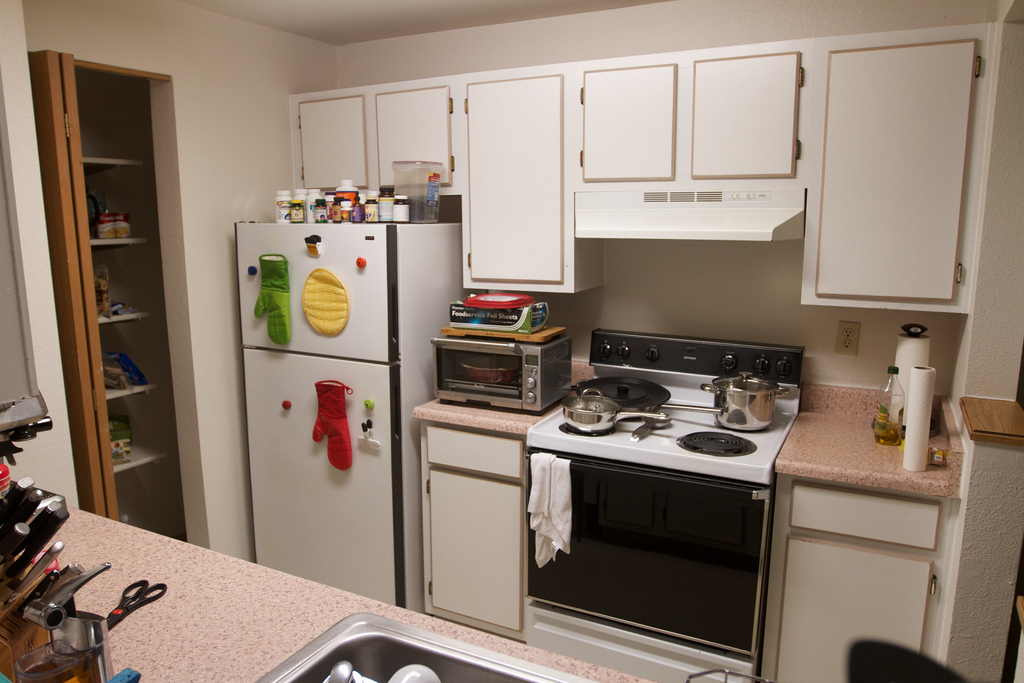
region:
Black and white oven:
[526, 325, 806, 680]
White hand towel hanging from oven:
[527, 447, 578, 577]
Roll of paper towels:
[902, 358, 937, 480]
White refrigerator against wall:
[235, 217, 469, 617]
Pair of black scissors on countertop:
[99, 575, 167, 632]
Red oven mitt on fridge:
[308, 374, 360, 474]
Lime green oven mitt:
[248, 252, 299, 351]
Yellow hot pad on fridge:
[301, 267, 353, 341]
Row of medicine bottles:
[270, 179, 413, 225]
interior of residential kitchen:
[4, 0, 1020, 677]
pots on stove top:
[525, 323, 804, 679]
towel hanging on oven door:
[523, 450, 774, 679]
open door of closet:
[29, 48, 206, 539]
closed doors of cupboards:
[283, 22, 1015, 314]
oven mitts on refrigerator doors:
[237, 223, 400, 598]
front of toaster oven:
[430, 335, 567, 413]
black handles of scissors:
[108, 577, 169, 625]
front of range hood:
[572, 186, 807, 244]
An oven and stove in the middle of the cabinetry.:
[511, 311, 821, 669]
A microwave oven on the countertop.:
[428, 319, 556, 421]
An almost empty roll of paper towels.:
[899, 349, 947, 477]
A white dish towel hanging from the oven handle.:
[498, 439, 591, 577]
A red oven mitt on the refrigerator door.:
[304, 374, 365, 483]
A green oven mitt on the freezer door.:
[234, 241, 302, 350]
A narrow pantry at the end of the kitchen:
[2, 29, 224, 545]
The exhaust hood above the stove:
[544, 149, 813, 301]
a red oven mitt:
[291, 369, 361, 480]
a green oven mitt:
[247, 247, 298, 352]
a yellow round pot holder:
[302, 269, 354, 339]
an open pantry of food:
[24, 45, 218, 552]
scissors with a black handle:
[95, 572, 169, 645]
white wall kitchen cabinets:
[279, 23, 997, 328]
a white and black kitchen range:
[531, 320, 807, 679]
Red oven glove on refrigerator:
[311, 376, 356, 472]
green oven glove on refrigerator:
[251, 252, 289, 348]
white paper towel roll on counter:
[901, 363, 934, 471]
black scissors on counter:
[102, 578, 166, 635]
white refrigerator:
[235, 217, 463, 613]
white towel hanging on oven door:
[528, 451, 574, 570]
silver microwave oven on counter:
[428, 331, 572, 415]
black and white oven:
[523, 322, 808, 680]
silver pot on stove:
[699, 369, 791, 431]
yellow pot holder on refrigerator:
[299, 268, 348, 338]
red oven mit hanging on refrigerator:
[232, 214, 466, 613]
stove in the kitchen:
[520, 328, 795, 679]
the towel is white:
[529, 442, 572, 561]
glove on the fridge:
[307, 378, 349, 470]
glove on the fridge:
[250, 255, 289, 339]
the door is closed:
[239, 349, 395, 597]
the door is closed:
[469, 84, 556, 281]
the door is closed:
[424, 470, 517, 630]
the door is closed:
[590, 68, 673, 179]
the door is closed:
[820, 44, 975, 301]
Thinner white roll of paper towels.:
[900, 362, 936, 471]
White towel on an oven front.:
[526, 452, 574, 566]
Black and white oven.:
[521, 330, 801, 681]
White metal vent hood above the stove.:
[572, 188, 808, 240]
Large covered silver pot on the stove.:
[698, 369, 793, 428]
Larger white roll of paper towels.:
[888, 333, 934, 428]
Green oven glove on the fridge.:
[252, 252, 295, 344]